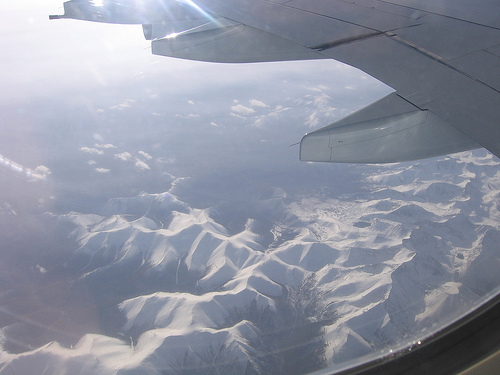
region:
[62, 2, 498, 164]
Grey wing of a plane.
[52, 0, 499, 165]
White wing of a plane.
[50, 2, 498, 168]
A light grey plane wing.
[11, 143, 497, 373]
White mountains below.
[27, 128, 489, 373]
Many white mountain ranges below.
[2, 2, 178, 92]
White sky above the mountains.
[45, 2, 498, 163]
A small portion of plane wing.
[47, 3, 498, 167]
A small white portion of plane wing.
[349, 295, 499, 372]
Part of the inside of the plane window.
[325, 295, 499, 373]
A black strip inside the plane window.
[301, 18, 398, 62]
The roof appears damaged.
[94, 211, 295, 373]
The snow is piled up.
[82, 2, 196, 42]
The sun is reflecting on the ice.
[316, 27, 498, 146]
The tile is in a rectangular shape.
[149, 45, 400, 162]
The snow is frozen in spots.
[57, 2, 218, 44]
There is ice reflecting the light.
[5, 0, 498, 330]
Snow is on the tile.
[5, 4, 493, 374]
A lot of snow is piled up.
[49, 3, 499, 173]
A grey section of plane wing.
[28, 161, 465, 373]
White mountains below.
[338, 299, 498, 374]
Black inner strip of window.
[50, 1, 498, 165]
A dark white plane wing.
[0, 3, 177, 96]
A white sky.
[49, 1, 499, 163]
A light grey plane wing.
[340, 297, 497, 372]
Black strip inside a window.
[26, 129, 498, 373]
White mountain range below.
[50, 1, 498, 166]
A grey airplane wing.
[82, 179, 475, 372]
Large white mountains below.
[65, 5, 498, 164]
Gray wing of airplane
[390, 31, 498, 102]
Seam on wing of plane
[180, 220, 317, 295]
White mountains below plane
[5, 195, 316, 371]
Range of white mountains below plane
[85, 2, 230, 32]
Sun reflection on plane wing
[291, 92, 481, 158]
Metal cover on plane engine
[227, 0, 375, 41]
Flap section on airplane wing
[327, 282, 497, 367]
Frame of window on plane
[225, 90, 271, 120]
White clouds in the sky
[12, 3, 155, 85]
Bright light from sun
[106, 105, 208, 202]
Clouds in the sky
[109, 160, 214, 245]
A window on the plane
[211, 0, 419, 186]
A wing on the plane